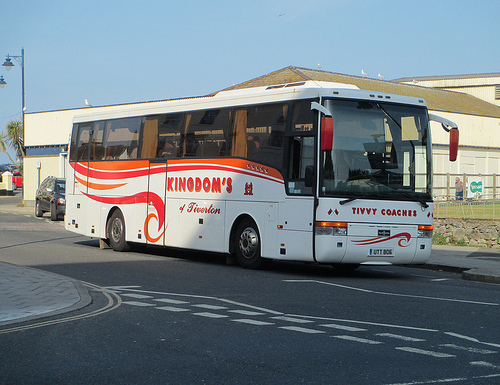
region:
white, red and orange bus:
[59, 94, 473, 267]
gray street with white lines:
[127, 268, 450, 375]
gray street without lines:
[25, 331, 235, 376]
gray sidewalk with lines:
[23, 262, 125, 337]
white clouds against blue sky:
[31, 10, 229, 82]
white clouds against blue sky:
[212, 10, 493, 63]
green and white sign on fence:
[459, 166, 495, 203]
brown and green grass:
[448, 205, 493, 218]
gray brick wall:
[447, 219, 499, 246]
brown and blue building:
[3, 112, 58, 173]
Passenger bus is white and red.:
[56, 82, 465, 278]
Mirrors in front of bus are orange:
[313, 119, 465, 168]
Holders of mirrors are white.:
[304, 95, 459, 123]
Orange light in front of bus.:
[311, 212, 446, 234]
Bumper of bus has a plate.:
[315, 234, 437, 264]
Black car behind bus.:
[27, 172, 69, 225]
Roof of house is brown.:
[258, 63, 493, 108]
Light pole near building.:
[3, 42, 30, 208]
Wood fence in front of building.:
[433, 168, 499, 210]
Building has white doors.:
[418, 141, 498, 191]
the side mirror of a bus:
[314, 104, 333, 151]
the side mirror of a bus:
[426, 111, 459, 167]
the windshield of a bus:
[325, 94, 435, 204]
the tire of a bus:
[228, 217, 261, 269]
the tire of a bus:
[105, 207, 130, 250]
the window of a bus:
[73, 121, 93, 168]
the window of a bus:
[104, 118, 141, 159]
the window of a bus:
[141, 116, 184, 157]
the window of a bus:
[182, 111, 234, 156]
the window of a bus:
[231, 109, 283, 166]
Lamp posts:
[1, 51, 31, 138]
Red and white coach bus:
[60, 93, 467, 271]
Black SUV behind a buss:
[33, 170, 66, 223]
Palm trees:
[0, 113, 23, 163]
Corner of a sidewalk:
[0, 235, 125, 333]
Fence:
[408, 170, 495, 200]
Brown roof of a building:
[210, 58, 496, 123]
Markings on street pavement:
[93, 265, 496, 382]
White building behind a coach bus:
[22, 65, 497, 210]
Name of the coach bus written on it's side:
[159, 161, 240, 238]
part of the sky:
[325, 11, 400, 53]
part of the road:
[209, 315, 271, 363]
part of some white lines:
[265, 291, 325, 329]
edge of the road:
[69, 265, 106, 295]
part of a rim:
[236, 226, 261, 258]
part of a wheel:
[236, 227, 261, 270]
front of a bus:
[343, 187, 428, 292]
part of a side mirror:
[310, 105, 348, 170]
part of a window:
[378, 133, 420, 168]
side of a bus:
[132, 143, 228, 257]